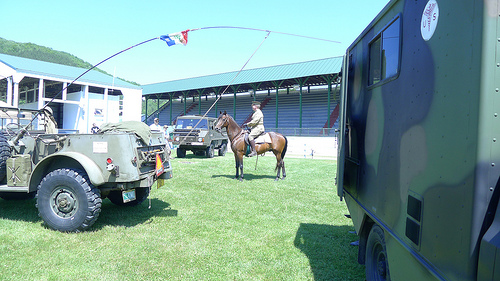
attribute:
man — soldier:
[245, 99, 264, 157]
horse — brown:
[215, 111, 286, 181]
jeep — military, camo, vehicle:
[1, 106, 172, 231]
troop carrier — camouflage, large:
[337, 1, 500, 279]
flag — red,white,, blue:
[160, 29, 190, 45]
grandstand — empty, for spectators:
[146, 89, 349, 136]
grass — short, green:
[3, 154, 361, 278]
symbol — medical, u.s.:
[421, 1, 440, 42]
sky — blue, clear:
[0, 0, 393, 85]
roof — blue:
[138, 56, 342, 95]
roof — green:
[143, 54, 344, 93]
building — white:
[1, 54, 143, 132]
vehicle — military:
[175, 115, 228, 156]